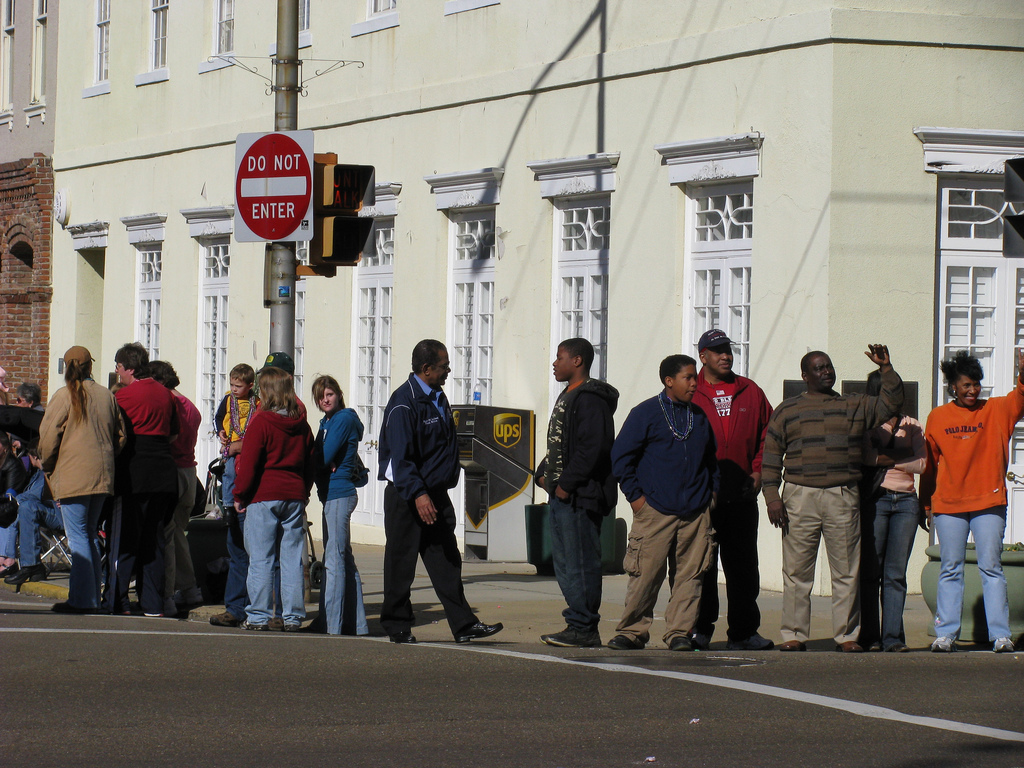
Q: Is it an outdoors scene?
A: Yes, it is outdoors.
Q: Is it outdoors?
A: Yes, it is outdoors.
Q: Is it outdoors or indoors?
A: It is outdoors.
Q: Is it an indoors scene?
A: No, it is outdoors.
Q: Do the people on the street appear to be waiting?
A: Yes, the people are waiting.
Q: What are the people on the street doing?
A: The people are waiting.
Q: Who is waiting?
A: The people are waiting.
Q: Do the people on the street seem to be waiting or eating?
A: The people are waiting.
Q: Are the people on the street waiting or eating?
A: The people are waiting.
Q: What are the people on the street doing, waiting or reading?
A: The people are waiting.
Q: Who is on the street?
A: The people are on the street.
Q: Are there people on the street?
A: Yes, there are people on the street.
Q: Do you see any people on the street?
A: Yes, there are people on the street.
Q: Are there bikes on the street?
A: No, there are people on the street.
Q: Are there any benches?
A: No, there are no benches.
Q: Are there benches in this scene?
A: No, there are no benches.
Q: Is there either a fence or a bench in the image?
A: No, there are no benches or fences.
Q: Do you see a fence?
A: No, there are no fences.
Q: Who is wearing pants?
A: The man is wearing pants.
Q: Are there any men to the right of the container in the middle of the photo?
A: Yes, there is a man to the right of the box.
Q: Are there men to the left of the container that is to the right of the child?
A: No, the man is to the right of the box.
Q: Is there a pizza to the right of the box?
A: No, there is a man to the right of the box.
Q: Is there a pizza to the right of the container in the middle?
A: No, there is a man to the right of the box.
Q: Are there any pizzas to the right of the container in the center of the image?
A: No, there is a man to the right of the box.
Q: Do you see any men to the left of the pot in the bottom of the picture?
A: Yes, there is a man to the left of the pot.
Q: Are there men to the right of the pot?
A: No, the man is to the left of the pot.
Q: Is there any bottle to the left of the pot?
A: No, there is a man to the left of the pot.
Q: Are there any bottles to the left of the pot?
A: No, there is a man to the left of the pot.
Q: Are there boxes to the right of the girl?
A: Yes, there is a box to the right of the girl.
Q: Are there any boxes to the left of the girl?
A: No, the box is to the right of the girl.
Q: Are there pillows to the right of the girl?
A: No, there is a box to the right of the girl.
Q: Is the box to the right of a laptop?
A: No, the box is to the right of the girl.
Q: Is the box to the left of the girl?
A: No, the box is to the right of the girl.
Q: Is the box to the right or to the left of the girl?
A: The box is to the right of the girl.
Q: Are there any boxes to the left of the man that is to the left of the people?
A: Yes, there is a box to the left of the man.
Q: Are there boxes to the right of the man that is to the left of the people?
A: No, the box is to the left of the man.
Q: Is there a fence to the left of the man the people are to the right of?
A: No, there is a box to the left of the man.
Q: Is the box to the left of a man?
A: Yes, the box is to the left of a man.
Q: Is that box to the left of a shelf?
A: No, the box is to the left of a man.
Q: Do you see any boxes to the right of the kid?
A: Yes, there is a box to the right of the kid.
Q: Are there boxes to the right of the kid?
A: Yes, there is a box to the right of the kid.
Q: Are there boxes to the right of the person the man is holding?
A: Yes, there is a box to the right of the kid.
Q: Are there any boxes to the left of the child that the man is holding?
A: No, the box is to the right of the child.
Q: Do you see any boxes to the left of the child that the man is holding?
A: No, the box is to the right of the child.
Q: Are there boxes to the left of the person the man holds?
A: No, the box is to the right of the child.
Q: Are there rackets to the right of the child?
A: No, there is a box to the right of the child.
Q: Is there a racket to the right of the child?
A: No, there is a box to the right of the child.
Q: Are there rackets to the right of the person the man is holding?
A: No, there is a box to the right of the child.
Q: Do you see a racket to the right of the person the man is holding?
A: No, there is a box to the right of the child.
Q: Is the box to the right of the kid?
A: Yes, the box is to the right of the kid.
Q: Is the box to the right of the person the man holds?
A: Yes, the box is to the right of the kid.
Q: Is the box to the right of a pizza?
A: No, the box is to the right of the kid.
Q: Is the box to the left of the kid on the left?
A: No, the box is to the right of the child.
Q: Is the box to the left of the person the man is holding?
A: No, the box is to the right of the child.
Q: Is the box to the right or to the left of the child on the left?
A: The box is to the right of the kid.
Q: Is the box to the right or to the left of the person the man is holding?
A: The box is to the right of the kid.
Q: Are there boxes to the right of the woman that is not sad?
A: Yes, there is a box to the right of the woman.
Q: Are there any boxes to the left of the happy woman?
A: No, the box is to the right of the woman.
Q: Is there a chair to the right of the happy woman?
A: No, there is a box to the right of the woman.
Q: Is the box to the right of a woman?
A: Yes, the box is to the right of a woman.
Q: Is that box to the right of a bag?
A: No, the box is to the right of a woman.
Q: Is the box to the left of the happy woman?
A: No, the box is to the right of the woman.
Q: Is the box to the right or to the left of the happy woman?
A: The box is to the right of the woman.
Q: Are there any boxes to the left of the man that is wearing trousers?
A: Yes, there is a box to the left of the man.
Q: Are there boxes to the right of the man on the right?
A: No, the box is to the left of the man.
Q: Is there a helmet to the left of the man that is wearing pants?
A: No, there is a box to the left of the man.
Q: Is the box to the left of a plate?
A: No, the box is to the left of a man.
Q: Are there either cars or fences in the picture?
A: No, there are no cars or fences.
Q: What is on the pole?
A: The sign is on the pole.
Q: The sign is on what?
A: The sign is on the pole.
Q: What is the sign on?
A: The sign is on the pole.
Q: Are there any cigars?
A: No, there are no cigars.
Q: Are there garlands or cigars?
A: No, there are no cigars or garlands.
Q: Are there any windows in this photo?
A: Yes, there are windows.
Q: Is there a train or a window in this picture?
A: Yes, there are windows.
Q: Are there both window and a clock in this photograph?
A: No, there are windows but no clocks.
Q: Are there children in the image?
A: Yes, there is a child.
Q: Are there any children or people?
A: Yes, there is a child.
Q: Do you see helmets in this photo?
A: No, there are no helmets.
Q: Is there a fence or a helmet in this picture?
A: No, there are no helmets or fences.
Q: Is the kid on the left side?
A: Yes, the kid is on the left of the image.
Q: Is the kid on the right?
A: No, the kid is on the left of the image.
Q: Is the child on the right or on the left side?
A: The child is on the left of the image.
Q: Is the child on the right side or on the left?
A: The child is on the left of the image.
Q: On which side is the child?
A: The child is on the left of the image.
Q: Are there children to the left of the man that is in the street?
A: Yes, there is a child to the left of the man.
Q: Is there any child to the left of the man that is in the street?
A: Yes, there is a child to the left of the man.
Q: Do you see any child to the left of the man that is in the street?
A: Yes, there is a child to the left of the man.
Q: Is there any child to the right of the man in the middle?
A: No, the child is to the left of the man.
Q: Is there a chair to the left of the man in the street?
A: No, there is a child to the left of the man.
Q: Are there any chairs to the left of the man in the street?
A: No, there is a child to the left of the man.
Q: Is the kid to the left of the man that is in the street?
A: Yes, the kid is to the left of the man.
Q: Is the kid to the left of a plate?
A: No, the kid is to the left of the man.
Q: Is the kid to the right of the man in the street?
A: No, the kid is to the left of the man.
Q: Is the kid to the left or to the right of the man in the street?
A: The kid is to the left of the man.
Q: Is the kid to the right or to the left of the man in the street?
A: The kid is to the left of the man.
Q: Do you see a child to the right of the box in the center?
A: No, the child is to the left of the box.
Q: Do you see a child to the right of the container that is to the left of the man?
A: No, the child is to the left of the box.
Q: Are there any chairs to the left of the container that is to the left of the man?
A: No, there is a child to the left of the box.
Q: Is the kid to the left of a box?
A: Yes, the kid is to the left of a box.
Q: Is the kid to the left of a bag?
A: No, the kid is to the left of a box.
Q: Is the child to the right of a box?
A: No, the child is to the left of a box.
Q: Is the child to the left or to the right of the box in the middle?
A: The child is to the left of the box.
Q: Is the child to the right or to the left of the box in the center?
A: The child is to the left of the box.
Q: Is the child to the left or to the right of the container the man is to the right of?
A: The child is to the left of the box.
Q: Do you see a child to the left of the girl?
A: Yes, there is a child to the left of the girl.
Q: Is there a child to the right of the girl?
A: No, the child is to the left of the girl.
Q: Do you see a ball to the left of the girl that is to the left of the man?
A: No, there is a child to the left of the girl.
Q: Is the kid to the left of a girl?
A: Yes, the kid is to the left of a girl.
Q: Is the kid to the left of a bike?
A: No, the kid is to the left of a girl.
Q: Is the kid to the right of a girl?
A: No, the kid is to the left of a girl.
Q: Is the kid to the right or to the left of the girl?
A: The kid is to the left of the girl.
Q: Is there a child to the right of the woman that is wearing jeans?
A: Yes, there is a child to the right of the woman.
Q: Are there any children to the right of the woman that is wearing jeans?
A: Yes, there is a child to the right of the woman.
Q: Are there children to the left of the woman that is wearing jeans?
A: No, the child is to the right of the woman.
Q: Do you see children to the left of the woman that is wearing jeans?
A: No, the child is to the right of the woman.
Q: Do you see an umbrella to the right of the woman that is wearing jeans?
A: No, there is a child to the right of the woman.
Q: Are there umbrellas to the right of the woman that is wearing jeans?
A: No, there is a child to the right of the woman.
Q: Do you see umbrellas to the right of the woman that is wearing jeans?
A: No, there is a child to the right of the woman.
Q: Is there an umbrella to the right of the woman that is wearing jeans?
A: No, there is a child to the right of the woman.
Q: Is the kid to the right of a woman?
A: Yes, the kid is to the right of a woman.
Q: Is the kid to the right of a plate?
A: No, the kid is to the right of a woman.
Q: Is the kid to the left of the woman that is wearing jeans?
A: No, the kid is to the right of the woman.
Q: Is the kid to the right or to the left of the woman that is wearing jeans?
A: The kid is to the right of the woman.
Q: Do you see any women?
A: Yes, there is a woman.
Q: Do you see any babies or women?
A: Yes, there is a woman.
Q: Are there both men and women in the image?
A: Yes, there are both a woman and a man.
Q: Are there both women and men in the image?
A: Yes, there are both a woman and a man.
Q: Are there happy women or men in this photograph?
A: Yes, there is a happy woman.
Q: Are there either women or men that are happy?
A: Yes, the woman is happy.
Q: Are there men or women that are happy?
A: Yes, the woman is happy.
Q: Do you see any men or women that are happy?
A: Yes, the woman is happy.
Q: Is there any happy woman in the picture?
A: Yes, there is a happy woman.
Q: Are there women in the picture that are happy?
A: Yes, there is a woman that is happy.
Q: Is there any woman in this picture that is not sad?
A: Yes, there is a happy woman.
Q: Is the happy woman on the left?
A: Yes, the woman is on the left of the image.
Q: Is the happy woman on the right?
A: No, the woman is on the left of the image.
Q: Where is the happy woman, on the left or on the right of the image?
A: The woman is on the left of the image.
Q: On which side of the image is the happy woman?
A: The woman is on the left of the image.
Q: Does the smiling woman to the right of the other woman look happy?
A: Yes, the woman is happy.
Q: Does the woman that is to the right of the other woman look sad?
A: No, the woman is happy.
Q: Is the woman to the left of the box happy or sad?
A: The woman is happy.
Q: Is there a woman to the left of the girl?
A: Yes, there is a woman to the left of the girl.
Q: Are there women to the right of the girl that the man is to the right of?
A: No, the woman is to the left of the girl.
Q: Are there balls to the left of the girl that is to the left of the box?
A: No, there is a woman to the left of the girl.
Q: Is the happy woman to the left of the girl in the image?
A: Yes, the woman is to the left of the girl.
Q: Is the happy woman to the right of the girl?
A: No, the woman is to the left of the girl.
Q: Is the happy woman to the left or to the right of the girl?
A: The woman is to the left of the girl.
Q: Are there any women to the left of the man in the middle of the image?
A: Yes, there is a woman to the left of the man.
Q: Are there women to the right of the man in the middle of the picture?
A: No, the woman is to the left of the man.